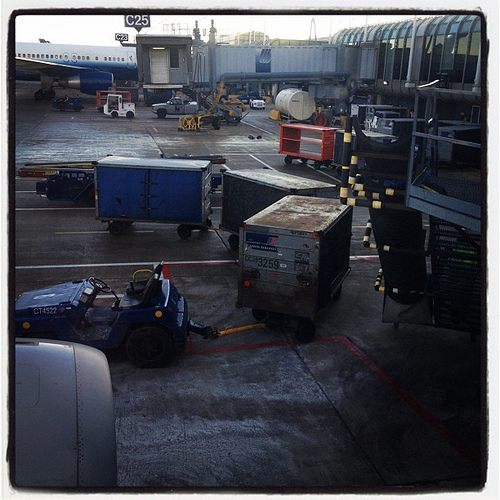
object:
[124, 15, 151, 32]
sign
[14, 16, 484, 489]
airport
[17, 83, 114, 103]
jetway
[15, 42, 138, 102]
plane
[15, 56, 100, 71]
wing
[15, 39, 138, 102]
airplane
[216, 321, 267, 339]
tow bar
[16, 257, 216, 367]
cart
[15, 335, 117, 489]
jet engine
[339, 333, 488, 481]
red line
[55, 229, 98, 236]
yellow line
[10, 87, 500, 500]
ground